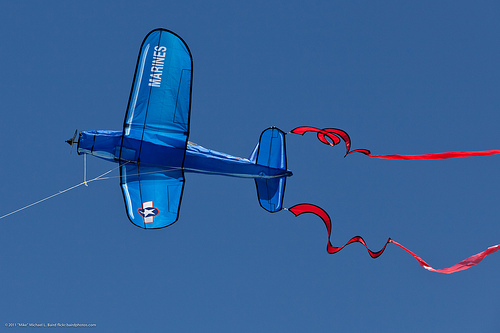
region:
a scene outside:
[4, 1, 481, 331]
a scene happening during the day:
[4, 9, 494, 322]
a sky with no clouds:
[8, 5, 497, 326]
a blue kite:
[30, 16, 499, 301]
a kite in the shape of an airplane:
[60, 17, 297, 258]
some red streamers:
[279, 110, 496, 300]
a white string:
[2, 138, 154, 248]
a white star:
[126, 194, 166, 229]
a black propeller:
[52, 118, 96, 175]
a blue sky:
[357, 51, 499, 111]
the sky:
[180, 229, 309, 323]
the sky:
[232, 300, 306, 330]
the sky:
[223, 233, 350, 324]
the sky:
[260, 194, 368, 294]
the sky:
[177, 201, 261, 315]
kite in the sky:
[98, 38, 498, 296]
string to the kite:
[5, 131, 133, 211]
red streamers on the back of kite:
[300, 121, 482, 289]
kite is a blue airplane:
[26, 16, 323, 222]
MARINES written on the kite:
[132, 26, 187, 94]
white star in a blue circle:
[125, 195, 180, 240]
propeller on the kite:
[41, 126, 81, 154]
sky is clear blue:
[247, 41, 463, 99]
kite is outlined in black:
[86, 18, 371, 250]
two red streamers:
[299, 117, 498, 277]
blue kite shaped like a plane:
[10, 5, 499, 327]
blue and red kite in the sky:
[8, 10, 493, 330]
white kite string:
[7, 152, 122, 234]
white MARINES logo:
[139, 21, 174, 94]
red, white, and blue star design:
[134, 192, 161, 234]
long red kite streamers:
[292, 110, 499, 295]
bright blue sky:
[205, 10, 485, 115]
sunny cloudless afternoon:
[205, 10, 491, 122]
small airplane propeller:
[58, 125, 84, 165]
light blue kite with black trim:
[42, 13, 300, 280]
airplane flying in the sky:
[20, 25, 465, 282]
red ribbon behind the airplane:
[289, 73, 499, 300]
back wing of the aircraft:
[212, 128, 311, 212]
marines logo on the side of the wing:
[116, 15, 262, 126]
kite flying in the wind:
[15, 25, 342, 296]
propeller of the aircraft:
[62, 102, 138, 209]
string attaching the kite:
[20, 131, 113, 237]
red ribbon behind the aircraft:
[282, 92, 499, 189]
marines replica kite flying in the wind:
[67, 20, 377, 202]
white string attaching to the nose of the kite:
[0, 89, 133, 242]